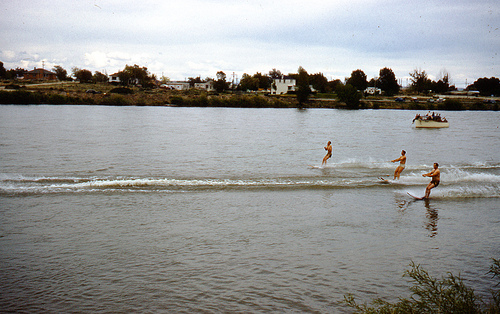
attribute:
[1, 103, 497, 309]
water — green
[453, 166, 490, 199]
ocean waves — white, blue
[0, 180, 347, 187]
wave — white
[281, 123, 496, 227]
people — three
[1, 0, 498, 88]
clouds — white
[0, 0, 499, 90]
sky — blue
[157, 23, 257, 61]
sky — blue 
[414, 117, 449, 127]
boat — white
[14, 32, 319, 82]
clouds — white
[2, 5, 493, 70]
sky — blue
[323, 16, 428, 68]
clouds — white 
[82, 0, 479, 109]
sky — blue 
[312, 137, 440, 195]
surfers — these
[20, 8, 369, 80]
clouds — white 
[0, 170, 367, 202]
wave — white, blue